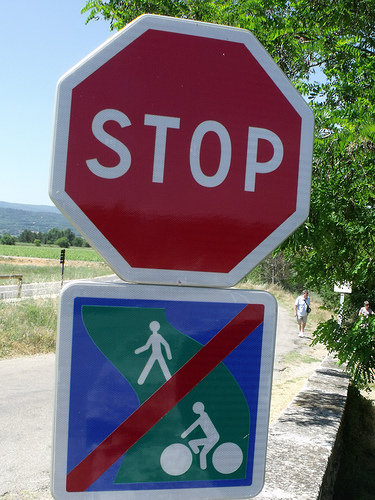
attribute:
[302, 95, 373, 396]
leaves — green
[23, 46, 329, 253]
sign — square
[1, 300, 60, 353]
grass — brown